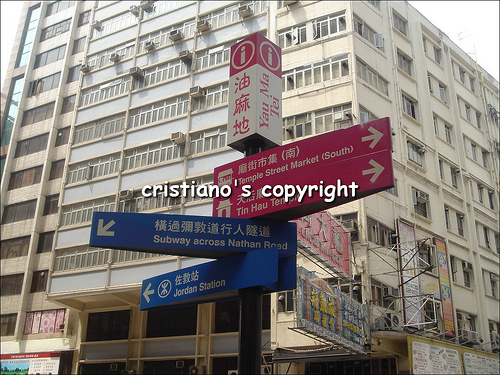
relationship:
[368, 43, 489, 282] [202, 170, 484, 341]
windows are windows here that are visible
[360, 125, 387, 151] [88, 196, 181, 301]
arrow pointing down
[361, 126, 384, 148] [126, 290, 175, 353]
arrow pointing right